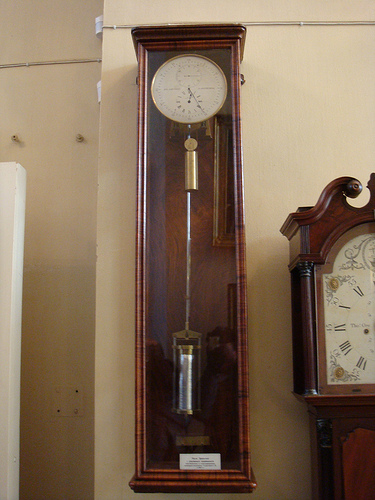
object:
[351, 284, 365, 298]
roman numerals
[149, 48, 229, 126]
clock face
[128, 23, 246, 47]
trim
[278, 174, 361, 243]
trim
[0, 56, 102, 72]
pipe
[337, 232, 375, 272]
design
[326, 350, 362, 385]
design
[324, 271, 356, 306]
design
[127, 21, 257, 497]
brown clock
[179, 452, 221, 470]
white card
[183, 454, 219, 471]
black writing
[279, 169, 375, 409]
clock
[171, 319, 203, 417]
pendulum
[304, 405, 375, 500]
stand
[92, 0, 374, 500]
wall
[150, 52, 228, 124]
dials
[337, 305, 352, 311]
numerals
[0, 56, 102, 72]
cord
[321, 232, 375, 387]
face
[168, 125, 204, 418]
chime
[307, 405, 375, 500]
case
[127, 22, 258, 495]
frame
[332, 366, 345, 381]
mark